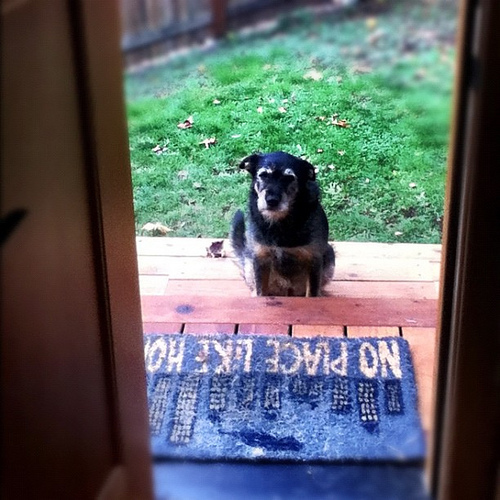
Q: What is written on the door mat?
A: No place like home.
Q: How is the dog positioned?
A: Sitting.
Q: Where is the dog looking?
A: At camera.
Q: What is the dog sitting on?
A: Deck.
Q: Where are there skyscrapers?
A: On mat.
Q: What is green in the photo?
A: Grass.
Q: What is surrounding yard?
A: Wood fence.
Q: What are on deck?
A: Wooden planks.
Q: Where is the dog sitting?
A: On step.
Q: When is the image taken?
A: Dog is sitting.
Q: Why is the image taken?
A: Remembrance.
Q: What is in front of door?
A: Mat.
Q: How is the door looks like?
A: Open.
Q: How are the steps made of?
A: Wood.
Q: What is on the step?
A: A black and tan dog.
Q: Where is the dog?
A: Sitting outside on a step.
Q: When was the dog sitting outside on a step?
A: Late morning.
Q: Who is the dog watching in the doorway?
A: A homeowner.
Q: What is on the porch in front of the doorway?
A: A mat.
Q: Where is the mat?
A: The porch.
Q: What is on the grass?
A: Brown leaves.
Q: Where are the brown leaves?
A: Green grass on the lawn.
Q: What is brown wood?
A: The door.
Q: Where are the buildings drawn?
A: On the floor mat.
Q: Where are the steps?
A: On the porch.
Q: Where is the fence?
A: By the grass.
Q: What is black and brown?
A: The dog.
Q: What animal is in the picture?
A: A dog.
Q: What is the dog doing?
A: Sitting at the doorstep.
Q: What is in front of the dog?
A: A welcome mat.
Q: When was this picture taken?
A: Daytime.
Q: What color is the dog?
A: Black and brown.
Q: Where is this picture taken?
A: A doorstep.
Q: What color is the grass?
A: Green.